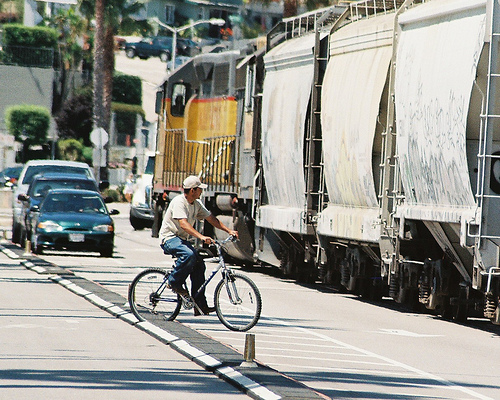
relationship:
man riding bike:
[149, 169, 219, 254] [137, 251, 267, 337]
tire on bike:
[212, 279, 271, 328] [137, 251, 267, 337]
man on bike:
[149, 169, 219, 254] [137, 251, 267, 337]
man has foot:
[149, 169, 219, 254] [163, 274, 192, 297]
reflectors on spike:
[246, 287, 254, 301] [234, 306, 247, 317]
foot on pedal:
[163, 274, 192, 297] [171, 291, 196, 305]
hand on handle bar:
[197, 221, 216, 248] [208, 232, 231, 256]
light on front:
[42, 216, 63, 232] [43, 225, 116, 248]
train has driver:
[159, 34, 444, 213] [164, 90, 188, 112]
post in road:
[91, 154, 107, 177] [293, 334, 374, 399]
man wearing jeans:
[149, 169, 219, 254] [174, 237, 205, 279]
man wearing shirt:
[149, 169, 219, 254] [173, 206, 202, 224]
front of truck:
[23, 163, 53, 174] [30, 159, 84, 168]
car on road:
[31, 181, 117, 249] [293, 334, 374, 399]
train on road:
[159, 34, 444, 213] [293, 334, 374, 399]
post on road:
[91, 154, 107, 177] [293, 334, 374, 399]